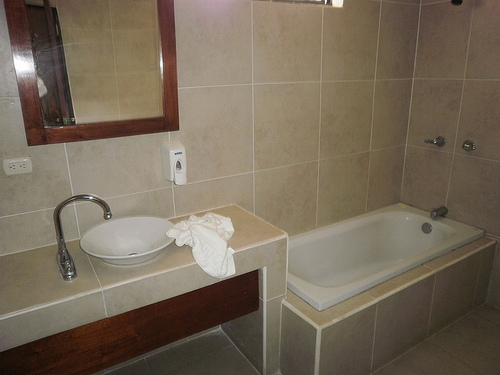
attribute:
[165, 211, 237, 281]
towel — white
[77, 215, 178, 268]
sink — round, white, clean, silvery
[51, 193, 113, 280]
faucet — silver, curved, clean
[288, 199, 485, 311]
tub — porcelain, white, cornered, clean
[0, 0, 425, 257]
wall — tiled, clean, light brown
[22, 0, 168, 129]
mirror — reflective, clean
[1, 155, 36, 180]
outlet — white, electrical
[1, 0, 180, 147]
wood — brown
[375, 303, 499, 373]
floor — clean, brown, tiled